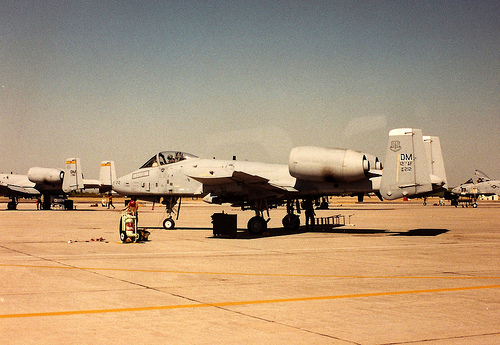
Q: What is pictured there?
A: Airplanes.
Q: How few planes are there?
A: 4.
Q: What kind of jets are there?
A: Fighter jets.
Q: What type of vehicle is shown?
A: Plane.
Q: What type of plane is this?
A: Fighter jet.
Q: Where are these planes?
A: Tarmac.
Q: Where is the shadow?
A: Under the plane.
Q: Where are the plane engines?
A: Back of plane.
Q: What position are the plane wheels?
A: Down.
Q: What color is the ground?
A: Yellow and gray.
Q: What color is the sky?
A: Blue.